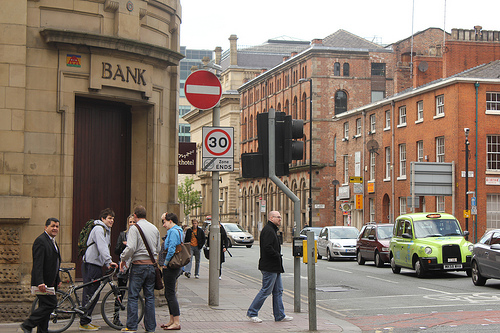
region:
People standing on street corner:
[18, 201, 193, 331]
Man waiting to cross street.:
[245, 205, 289, 328]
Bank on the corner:
[0, 0, 181, 314]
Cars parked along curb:
[292, 208, 498, 289]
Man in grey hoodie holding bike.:
[49, 204, 144, 329]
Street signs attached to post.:
[185, 50, 241, 310]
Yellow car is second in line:
[387, 208, 467, 280]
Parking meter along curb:
[290, 221, 304, 317]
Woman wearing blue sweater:
[157, 206, 183, 331]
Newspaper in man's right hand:
[23, 279, 59, 303]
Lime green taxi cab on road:
[389, 210, 471, 278]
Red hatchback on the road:
[353, 221, 392, 264]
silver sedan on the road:
[318, 223, 359, 263]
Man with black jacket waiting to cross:
[245, 208, 298, 326]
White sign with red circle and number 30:
[200, 124, 231, 158]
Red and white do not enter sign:
[184, 68, 221, 111]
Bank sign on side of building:
[92, 57, 151, 90]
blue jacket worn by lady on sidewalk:
[160, 224, 190, 261]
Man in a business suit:
[25, 217, 67, 329]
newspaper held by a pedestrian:
[25, 283, 58, 296]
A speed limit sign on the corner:
[199, 123, 238, 160]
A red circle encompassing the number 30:
[204, 127, 234, 157]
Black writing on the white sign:
[210, 135, 231, 150]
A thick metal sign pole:
[199, 172, 231, 304]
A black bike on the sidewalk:
[45, 260, 157, 328]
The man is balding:
[268, 210, 290, 219]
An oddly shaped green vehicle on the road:
[387, 207, 479, 272]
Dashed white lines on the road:
[367, 272, 449, 294]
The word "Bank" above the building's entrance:
[89, 57, 159, 98]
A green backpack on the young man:
[79, 215, 97, 255]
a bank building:
[37, 0, 176, 210]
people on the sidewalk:
[2, 195, 234, 330]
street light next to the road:
[241, 109, 313, 331]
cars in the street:
[318, 214, 499, 289]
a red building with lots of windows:
[336, 56, 498, 238]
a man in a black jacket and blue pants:
[243, 205, 302, 325]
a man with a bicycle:
[63, 207, 125, 332]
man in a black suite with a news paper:
[21, 214, 76, 331]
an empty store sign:
[407, 152, 462, 210]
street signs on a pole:
[186, 62, 250, 314]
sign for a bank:
[100, 63, 151, 90]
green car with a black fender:
[397, 213, 471, 271]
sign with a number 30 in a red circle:
[206, 128, 230, 156]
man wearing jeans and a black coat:
[258, 210, 291, 322]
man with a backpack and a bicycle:
[75, 211, 120, 324]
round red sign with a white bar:
[185, 69, 223, 108]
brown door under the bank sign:
[78, 98, 128, 205]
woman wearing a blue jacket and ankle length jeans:
[161, 217, 188, 328]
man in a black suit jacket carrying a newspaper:
[31, 218, 58, 323]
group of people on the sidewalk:
[36, 212, 292, 322]